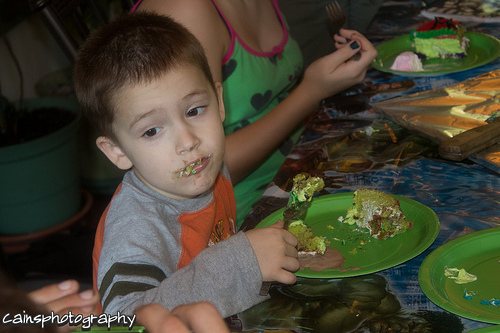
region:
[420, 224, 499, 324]
a green paper plate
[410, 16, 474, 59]
a slice of cake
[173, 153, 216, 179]
icing on boys mouth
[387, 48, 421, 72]
pink ice cream in plate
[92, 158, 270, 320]
a grey and orange shirt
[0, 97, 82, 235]
a green pot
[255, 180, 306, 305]
a metal fork with cake on it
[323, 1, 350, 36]
a clean metal fork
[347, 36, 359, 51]
a painted finger nail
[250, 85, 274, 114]
a heart on shirt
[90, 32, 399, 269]
little boy eating a cake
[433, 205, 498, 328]
a green plate with cake frosting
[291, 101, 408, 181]
a movie theme tablecloth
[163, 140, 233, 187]
boy with cake frosting smeared on his mouth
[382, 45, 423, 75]
a scoop of strawberry ice cream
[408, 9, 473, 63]
a piece of cake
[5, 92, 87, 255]
a green plant pot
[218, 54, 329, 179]
green tank top with heart patterns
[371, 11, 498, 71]
plate with ice cream and cake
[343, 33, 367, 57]
thumb nail painted with black nail polish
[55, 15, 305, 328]
the boy at the table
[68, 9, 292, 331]
the boy is young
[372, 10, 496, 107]
the cake on the table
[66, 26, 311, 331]
the boy is eating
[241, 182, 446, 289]
the cake on the plate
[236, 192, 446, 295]
the plate is green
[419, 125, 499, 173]
the handle of the knife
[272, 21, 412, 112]
the hand with black nail polish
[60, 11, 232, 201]
the boy has short hair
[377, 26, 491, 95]
the cake on the plate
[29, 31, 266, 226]
a cute little boy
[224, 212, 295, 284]
hand of a boy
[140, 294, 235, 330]
two fingers of a person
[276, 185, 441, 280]
a green plate with food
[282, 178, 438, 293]
left over food items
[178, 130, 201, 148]
nose of the preson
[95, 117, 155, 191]
ear of the boy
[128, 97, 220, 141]
two eyes of the boy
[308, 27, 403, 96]
hand of the girl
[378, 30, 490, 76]
a small cake piece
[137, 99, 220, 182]
the face of a child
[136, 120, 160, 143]
the eye of a child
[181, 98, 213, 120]
the eye of a child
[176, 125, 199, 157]
the nose of a child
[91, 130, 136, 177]
the ear of a child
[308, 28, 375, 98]
the hand of a person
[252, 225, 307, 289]
the hand of a child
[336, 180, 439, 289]
a green plate on a table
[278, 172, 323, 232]
food on a fork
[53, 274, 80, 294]
a finger nail on a finger